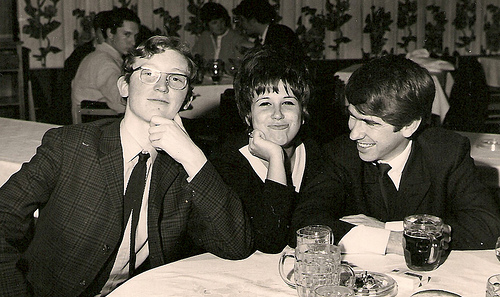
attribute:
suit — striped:
[40, 141, 105, 265]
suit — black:
[321, 149, 425, 198]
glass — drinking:
[394, 221, 446, 267]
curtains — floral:
[300, 9, 489, 49]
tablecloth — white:
[183, 275, 220, 287]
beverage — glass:
[400, 219, 439, 274]